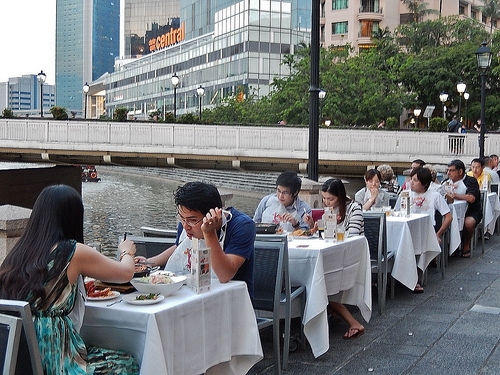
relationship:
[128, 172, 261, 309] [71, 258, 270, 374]
man sits at table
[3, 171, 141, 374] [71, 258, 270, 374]
woman sits at table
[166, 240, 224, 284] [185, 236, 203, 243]
napkin under chin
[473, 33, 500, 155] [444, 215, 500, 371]
light in sidewalk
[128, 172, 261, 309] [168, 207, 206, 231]
man has glasses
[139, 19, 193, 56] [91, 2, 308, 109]
sign on top building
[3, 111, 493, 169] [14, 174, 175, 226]
bridge over water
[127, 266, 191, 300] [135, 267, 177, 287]
dish of rice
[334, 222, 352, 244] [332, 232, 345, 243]
mug has beer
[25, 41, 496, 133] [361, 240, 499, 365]
lights in street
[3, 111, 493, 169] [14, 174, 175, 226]
walkway across river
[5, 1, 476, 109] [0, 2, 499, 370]
buildings in city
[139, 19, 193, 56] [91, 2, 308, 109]
sign on building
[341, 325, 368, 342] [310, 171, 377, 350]
sandal of woman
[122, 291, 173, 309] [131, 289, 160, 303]
bowl of salad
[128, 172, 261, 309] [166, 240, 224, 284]
man has bib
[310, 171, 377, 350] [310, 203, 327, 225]
woman has menu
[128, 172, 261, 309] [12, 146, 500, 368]
man eats outdoors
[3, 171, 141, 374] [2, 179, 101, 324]
woman hs black hair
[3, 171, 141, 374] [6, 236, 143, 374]
woman wears aqua dress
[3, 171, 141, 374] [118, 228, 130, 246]
woman eats with chop sticks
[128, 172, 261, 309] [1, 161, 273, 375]
man in foreground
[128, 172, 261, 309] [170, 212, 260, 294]
man wears blue shirt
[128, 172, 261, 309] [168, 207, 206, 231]
man wears glasses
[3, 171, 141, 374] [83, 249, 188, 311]
woman eating dinner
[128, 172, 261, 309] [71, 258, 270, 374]
man eating at table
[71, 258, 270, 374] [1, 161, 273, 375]
table with two people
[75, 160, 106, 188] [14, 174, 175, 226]
boat on water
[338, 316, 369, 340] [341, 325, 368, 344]
foot with sandal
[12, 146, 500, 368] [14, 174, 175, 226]
people by water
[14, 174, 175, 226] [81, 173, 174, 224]
water has quakes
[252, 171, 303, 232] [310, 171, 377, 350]
man sitting beside woman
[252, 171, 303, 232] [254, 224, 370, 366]
man sitting at table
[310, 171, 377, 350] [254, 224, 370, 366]
woman sitting at table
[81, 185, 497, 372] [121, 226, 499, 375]
tablecloths on tables